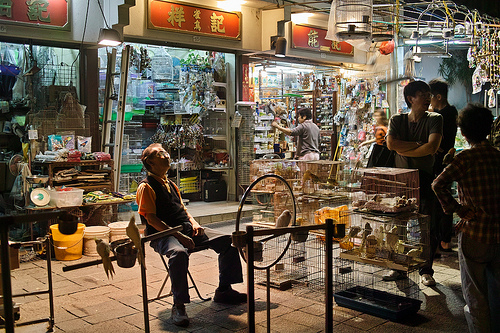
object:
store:
[96, 0, 261, 228]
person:
[430, 101, 499, 332]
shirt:
[430, 141, 500, 243]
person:
[380, 79, 443, 285]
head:
[140, 142, 172, 169]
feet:
[170, 304, 190, 326]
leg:
[160, 234, 191, 302]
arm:
[135, 184, 179, 237]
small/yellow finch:
[275, 207, 291, 225]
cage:
[337, 209, 431, 269]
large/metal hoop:
[234, 173, 297, 269]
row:
[49, 219, 138, 260]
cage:
[334, 256, 422, 320]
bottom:
[330, 284, 423, 318]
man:
[135, 142, 247, 325]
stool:
[154, 250, 212, 299]